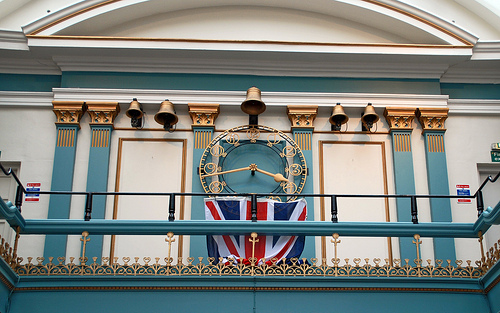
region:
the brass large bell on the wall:
[128, 97, 141, 117]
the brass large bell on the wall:
[154, 98, 176, 125]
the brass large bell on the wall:
[239, 84, 265, 116]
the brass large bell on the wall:
[330, 101, 347, 125]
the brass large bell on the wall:
[362, 104, 377, 122]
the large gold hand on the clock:
[200, 161, 252, 180]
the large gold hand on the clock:
[254, 166, 292, 188]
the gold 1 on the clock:
[266, 130, 277, 145]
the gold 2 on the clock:
[284, 146, 296, 156]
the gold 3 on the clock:
[287, 161, 302, 176]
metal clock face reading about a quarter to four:
[199, 123, 308, 209]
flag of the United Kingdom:
[203, 196, 307, 268]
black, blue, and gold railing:
[0, 167, 499, 278]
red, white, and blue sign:
[454, 182, 473, 204]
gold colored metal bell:
[238, 85, 266, 115]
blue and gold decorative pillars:
[43, 98, 456, 265]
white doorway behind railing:
[0, 162, 21, 268]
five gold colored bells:
[124, 85, 379, 134]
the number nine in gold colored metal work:
[203, 160, 220, 177]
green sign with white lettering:
[487, 142, 499, 164]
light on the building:
[353, 94, 375, 131]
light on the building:
[327, 105, 351, 131]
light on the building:
[237, 90, 267, 123]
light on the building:
[148, 99, 172, 132]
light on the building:
[115, 98, 141, 129]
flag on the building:
[200, 206, 277, 253]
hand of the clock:
[251, 161, 306, 181]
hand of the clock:
[202, 162, 249, 180]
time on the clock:
[276, 139, 301, 164]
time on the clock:
[172, 161, 288, 183]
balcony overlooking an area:
[41, 78, 475, 277]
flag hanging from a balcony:
[203, 183, 310, 268]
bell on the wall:
[358, 104, 381, 124]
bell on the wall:
[333, 85, 350, 136]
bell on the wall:
[158, 103, 180, 130]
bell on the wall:
[118, 93, 145, 123]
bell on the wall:
[233, 77, 277, 127]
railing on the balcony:
[29, 179, 495, 266]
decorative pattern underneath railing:
[19, 244, 491, 281]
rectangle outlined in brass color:
[315, 136, 396, 255]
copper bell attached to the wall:
[154, 95, 178, 132]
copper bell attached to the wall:
[241, 84, 265, 116]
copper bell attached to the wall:
[323, 99, 348, 135]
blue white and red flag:
[200, 191, 310, 269]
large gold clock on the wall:
[197, 124, 302, 196]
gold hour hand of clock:
[249, 161, 294, 193]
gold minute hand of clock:
[196, 154, 256, 189]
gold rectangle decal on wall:
[319, 137, 393, 264]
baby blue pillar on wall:
[48, 118, 80, 266]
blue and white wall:
[8, 92, 498, 264]